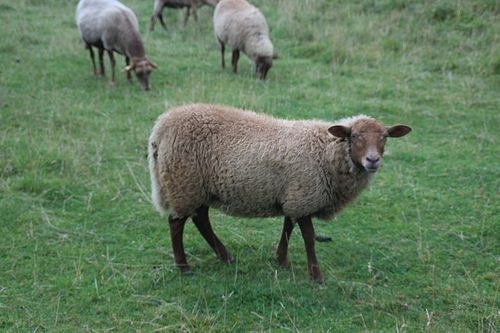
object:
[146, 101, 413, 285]
animal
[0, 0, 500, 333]
field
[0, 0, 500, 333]
pasture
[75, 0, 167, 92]
sheep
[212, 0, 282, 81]
sheep